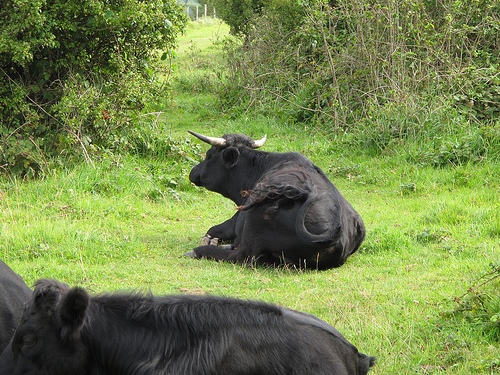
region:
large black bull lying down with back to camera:
[176, 119, 359, 270]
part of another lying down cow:
[0, 276, 378, 373]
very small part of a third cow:
[2, 259, 28, 371]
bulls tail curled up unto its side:
[256, 169, 336, 249]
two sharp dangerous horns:
[189, 127, 274, 146]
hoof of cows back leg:
[181, 247, 198, 266]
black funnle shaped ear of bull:
[216, 139, 243, 179]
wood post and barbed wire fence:
[167, 3, 225, 34]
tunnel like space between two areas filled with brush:
[148, 11, 254, 150]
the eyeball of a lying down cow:
[18, 327, 40, 353]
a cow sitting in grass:
[147, 104, 397, 335]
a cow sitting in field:
[150, 91, 431, 344]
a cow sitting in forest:
[142, 104, 399, 288]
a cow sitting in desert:
[167, 114, 354, 274]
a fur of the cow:
[139, 277, 279, 371]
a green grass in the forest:
[25, 170, 219, 289]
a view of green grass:
[262, 19, 477, 142]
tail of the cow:
[298, 217, 356, 269]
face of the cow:
[140, 93, 278, 200]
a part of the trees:
[6, 6, 188, 165]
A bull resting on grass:
[158, 116, 392, 278]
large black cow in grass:
[148, 98, 377, 252]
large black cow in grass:
[2, 291, 339, 374]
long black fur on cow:
[163, 297, 281, 373]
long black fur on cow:
[253, 167, 303, 222]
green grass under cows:
[78, 195, 496, 365]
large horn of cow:
[183, 123, 223, 148]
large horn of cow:
[248, 121, 281, 145]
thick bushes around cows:
[245, 19, 491, 119]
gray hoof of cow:
[185, 244, 201, 261]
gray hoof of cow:
[195, 234, 217, 247]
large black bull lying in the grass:
[175, 124, 369, 277]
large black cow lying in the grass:
[3, 268, 376, 373]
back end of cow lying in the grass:
[1, 259, 37, 373]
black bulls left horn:
[186, 125, 226, 147]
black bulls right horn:
[251, 135, 270, 147]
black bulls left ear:
[219, 146, 241, 172]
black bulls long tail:
[291, 184, 343, 246]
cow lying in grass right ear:
[55, 286, 93, 336]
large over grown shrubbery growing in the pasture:
[204, 0, 496, 164]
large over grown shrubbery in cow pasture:
[0, 0, 191, 187]